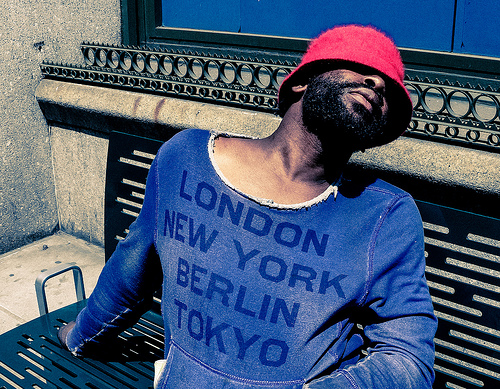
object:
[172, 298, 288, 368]
tokyo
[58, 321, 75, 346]
hand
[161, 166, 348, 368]
blue lettering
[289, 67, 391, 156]
head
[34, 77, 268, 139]
street wall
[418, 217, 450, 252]
ground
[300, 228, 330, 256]
lettering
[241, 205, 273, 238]
lettering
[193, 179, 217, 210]
lettering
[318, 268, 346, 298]
lettering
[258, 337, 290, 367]
lettering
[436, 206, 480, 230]
black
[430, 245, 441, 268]
metal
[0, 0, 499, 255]
wall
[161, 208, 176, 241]
lettering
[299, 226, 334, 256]
lettering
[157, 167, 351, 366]
text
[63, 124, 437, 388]
shirt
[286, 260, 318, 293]
blue letter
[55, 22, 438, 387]
man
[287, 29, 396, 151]
head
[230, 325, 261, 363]
lettering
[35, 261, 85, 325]
handle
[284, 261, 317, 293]
lettering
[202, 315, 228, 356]
lettering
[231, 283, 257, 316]
lettering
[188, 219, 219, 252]
lettering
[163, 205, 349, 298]
new york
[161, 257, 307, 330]
berlin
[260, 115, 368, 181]
neck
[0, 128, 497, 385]
bench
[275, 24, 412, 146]
hat